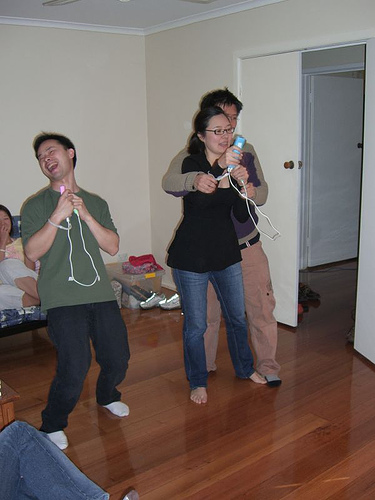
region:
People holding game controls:
[20, 86, 291, 449]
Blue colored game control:
[228, 137, 243, 172]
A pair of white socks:
[45, 400, 131, 449]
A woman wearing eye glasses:
[192, 107, 238, 157]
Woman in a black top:
[165, 105, 240, 271]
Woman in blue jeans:
[171, 257, 256, 389]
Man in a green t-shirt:
[16, 135, 121, 306]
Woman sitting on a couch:
[0, 204, 40, 309]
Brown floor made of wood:
[3, 297, 373, 497]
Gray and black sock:
[263, 370, 283, 388]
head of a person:
[13, 126, 85, 190]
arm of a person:
[30, 208, 65, 250]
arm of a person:
[73, 218, 113, 247]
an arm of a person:
[33, 206, 61, 251]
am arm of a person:
[73, 205, 106, 241]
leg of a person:
[38, 348, 95, 415]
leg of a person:
[87, 323, 125, 401]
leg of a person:
[172, 304, 209, 382]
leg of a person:
[214, 287, 246, 368]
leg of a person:
[240, 295, 286, 357]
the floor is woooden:
[153, 416, 320, 485]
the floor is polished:
[160, 423, 293, 485]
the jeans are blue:
[173, 272, 254, 380]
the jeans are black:
[41, 308, 139, 416]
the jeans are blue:
[9, 423, 94, 499]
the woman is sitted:
[2, 208, 45, 317]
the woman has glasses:
[164, 90, 274, 401]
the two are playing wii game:
[34, 110, 278, 427]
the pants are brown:
[240, 242, 293, 375]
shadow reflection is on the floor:
[102, 414, 140, 467]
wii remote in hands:
[227, 126, 242, 191]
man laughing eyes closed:
[27, 128, 86, 194]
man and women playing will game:
[161, 59, 307, 408]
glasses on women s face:
[206, 126, 234, 136]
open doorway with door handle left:
[279, 39, 371, 336]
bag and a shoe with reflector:
[126, 231, 164, 315]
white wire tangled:
[251, 208, 284, 243]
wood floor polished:
[286, 373, 371, 466]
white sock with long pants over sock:
[95, 385, 138, 421]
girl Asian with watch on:
[0, 183, 23, 312]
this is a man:
[10, 120, 126, 441]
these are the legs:
[52, 334, 129, 412]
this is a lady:
[160, 114, 250, 291]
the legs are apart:
[181, 273, 255, 364]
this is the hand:
[222, 145, 243, 161]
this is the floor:
[237, 415, 331, 496]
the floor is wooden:
[244, 423, 322, 494]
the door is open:
[290, 70, 372, 146]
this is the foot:
[104, 399, 130, 417]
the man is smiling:
[45, 158, 59, 172]